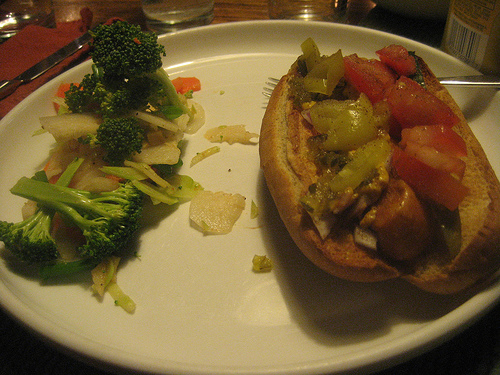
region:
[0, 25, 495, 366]
The plate is white.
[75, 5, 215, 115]
A piece of broccoli on the plate.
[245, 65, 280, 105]
The tines of a fork.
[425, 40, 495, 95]
The handle of the fork.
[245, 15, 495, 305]
A sandwich on a plate.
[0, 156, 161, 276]
Two florets of green broccolli.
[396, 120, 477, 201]
Some pieces of tomato on a sandwich.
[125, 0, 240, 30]
The base of a drinking glass.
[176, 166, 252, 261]
A piece of food on a plate.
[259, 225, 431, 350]
The shadow of a sandwich on a plate.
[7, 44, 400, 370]
a plate is white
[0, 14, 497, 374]
Food is on the plate.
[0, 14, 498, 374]
The plate is white.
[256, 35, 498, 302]
A sandwich is on the plate.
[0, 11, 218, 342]
Vegetables are on the plate.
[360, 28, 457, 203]
The sandwich contains peppers.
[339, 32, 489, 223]
The peppers are red.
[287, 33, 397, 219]
The sandwich contains onions.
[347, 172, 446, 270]
The sandwich contains sausage.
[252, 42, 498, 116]
A fork is on the plate.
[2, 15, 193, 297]
Broccoli is on the plate.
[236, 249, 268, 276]
small piece of onion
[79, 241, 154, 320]
green pieces of hot peppers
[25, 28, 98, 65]
edge of silver knife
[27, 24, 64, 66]
shiny brown surface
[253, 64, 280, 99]
tip of shiny fork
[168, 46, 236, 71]
small shine on white plate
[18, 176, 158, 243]
several green broccoli stalk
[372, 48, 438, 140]
sauteed red tomatoes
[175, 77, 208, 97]
tiny piece of orange carrot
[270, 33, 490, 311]
large lunch sandwich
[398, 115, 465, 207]
some nice red peppers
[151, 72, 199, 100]
these are orange carrots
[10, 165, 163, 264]
this is green broccoli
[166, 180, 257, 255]
these are white onions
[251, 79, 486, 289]
this is a hot dog bun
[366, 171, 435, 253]
this is a mushroom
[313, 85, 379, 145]
this is a green pepper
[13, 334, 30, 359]
this is the color black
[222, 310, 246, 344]
this is the color white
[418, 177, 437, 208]
this is the color red